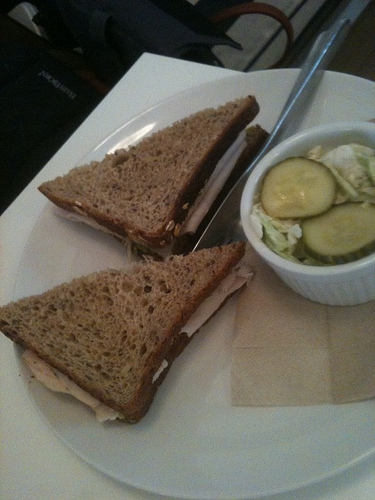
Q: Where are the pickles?
A: Round white dish.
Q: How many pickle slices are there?
A: Two.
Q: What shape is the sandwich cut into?
A: Triangle.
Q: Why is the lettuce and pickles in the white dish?
A: Customer adds their own lettuce and pickle.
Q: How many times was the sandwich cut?
A: Once.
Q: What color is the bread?
A: Brown.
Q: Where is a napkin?
A: Under round dish.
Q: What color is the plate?
A: White.